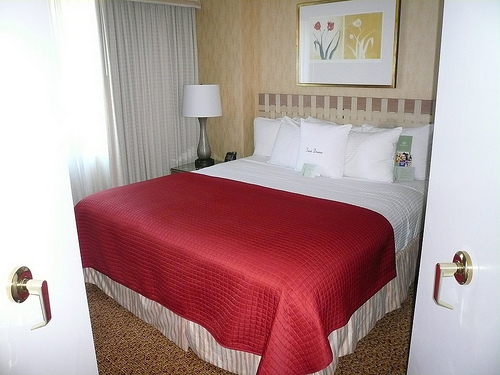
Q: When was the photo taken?
A: During the daytime.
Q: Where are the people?
A: None in photo.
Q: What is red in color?
A: The sheet.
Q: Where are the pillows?
A: On the bed.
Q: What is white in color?
A: Pillows.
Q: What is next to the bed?
A: Lamp.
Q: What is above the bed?
A: A painting.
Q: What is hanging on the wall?
A: A picture.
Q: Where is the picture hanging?
A: Over the bed.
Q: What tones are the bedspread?
A: Red and white?.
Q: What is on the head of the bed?
A: Pillows.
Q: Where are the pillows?
A: At the head of the bed.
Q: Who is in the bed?
A: Nobody.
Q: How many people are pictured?
A: 0.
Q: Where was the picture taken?
A: Bedroom.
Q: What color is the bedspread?
A: Red.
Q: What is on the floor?
A: Carpet.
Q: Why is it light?
A: Sun.